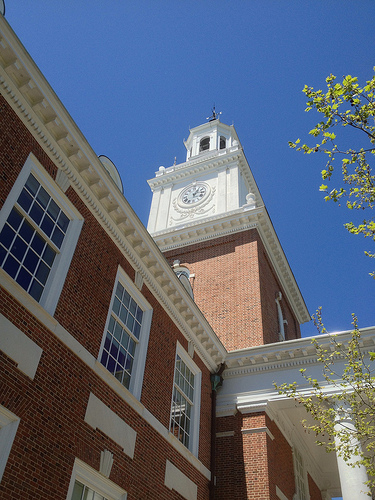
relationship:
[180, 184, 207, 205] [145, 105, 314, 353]
clock on tower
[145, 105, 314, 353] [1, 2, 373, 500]
tower on building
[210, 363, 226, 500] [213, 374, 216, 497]
rain gutter in corner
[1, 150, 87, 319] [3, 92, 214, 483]
window on upper floor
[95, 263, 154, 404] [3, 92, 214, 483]
window on upper floor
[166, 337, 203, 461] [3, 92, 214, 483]
window on upper floor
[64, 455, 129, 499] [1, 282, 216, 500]
window on ground floor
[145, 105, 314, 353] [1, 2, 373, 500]
tower on court house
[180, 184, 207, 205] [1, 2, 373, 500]
clock on top of court house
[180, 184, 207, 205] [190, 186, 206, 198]
clock reads 2:15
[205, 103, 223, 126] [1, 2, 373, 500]
vane on top of court house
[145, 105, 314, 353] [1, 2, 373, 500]
tower on top of court house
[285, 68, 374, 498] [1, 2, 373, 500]
tree next to court house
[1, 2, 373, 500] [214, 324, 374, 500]
court house has porch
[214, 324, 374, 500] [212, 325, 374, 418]
porch has awning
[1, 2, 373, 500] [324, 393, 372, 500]
court house has porch column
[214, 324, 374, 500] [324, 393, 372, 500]
porch has porch column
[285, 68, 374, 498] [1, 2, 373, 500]
tree in front of court house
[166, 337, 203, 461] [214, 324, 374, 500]
window next to porch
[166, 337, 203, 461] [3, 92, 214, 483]
window on 2nd floor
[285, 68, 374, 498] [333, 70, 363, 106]
branches have leaves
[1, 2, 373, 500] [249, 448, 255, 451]
building made of brick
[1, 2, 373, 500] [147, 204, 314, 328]
building has trim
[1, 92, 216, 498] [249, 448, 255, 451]
wall made of brick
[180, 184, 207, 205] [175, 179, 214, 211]
clockface on background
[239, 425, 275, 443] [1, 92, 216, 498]
decoration on wall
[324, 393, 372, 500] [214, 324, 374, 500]
column under a porticoshare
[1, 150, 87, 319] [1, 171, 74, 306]
window has 20 panes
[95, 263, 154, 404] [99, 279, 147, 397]
window has 20 panes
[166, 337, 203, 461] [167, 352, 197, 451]
window has 20 panes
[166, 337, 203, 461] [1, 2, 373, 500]
window in brick building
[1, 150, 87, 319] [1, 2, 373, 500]
window in brick building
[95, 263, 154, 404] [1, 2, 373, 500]
window in brick building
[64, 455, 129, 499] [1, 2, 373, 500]
window in brick building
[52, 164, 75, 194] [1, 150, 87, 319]
white decoration above window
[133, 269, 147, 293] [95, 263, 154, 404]
decoration above window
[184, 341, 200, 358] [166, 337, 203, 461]
decoration above window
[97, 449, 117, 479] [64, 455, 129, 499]
decoration above window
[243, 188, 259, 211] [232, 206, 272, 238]
decoration on eave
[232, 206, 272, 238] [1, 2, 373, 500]
eave on building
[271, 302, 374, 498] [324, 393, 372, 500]
foliage in front of column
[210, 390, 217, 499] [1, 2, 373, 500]
pipe on side of building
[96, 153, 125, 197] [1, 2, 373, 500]
window in building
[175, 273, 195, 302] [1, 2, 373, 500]
window in building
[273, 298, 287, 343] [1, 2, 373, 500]
window in building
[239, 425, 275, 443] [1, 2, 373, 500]
decoration on corner of building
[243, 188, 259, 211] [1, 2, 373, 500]
decoration on corner of building